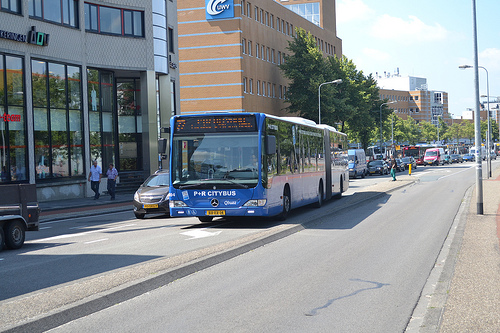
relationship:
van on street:
[423, 145, 446, 168] [340, 134, 473, 278]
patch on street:
[297, 241, 389, 324] [169, 226, 273, 302]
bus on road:
[167, 109, 352, 222] [0, 156, 498, 332]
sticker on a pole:
[472, 145, 484, 177] [466, 83, 493, 222]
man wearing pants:
[390, 155, 400, 182] [388, 168, 398, 182]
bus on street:
[164, 109, 354, 225] [1, 166, 483, 331]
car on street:
[132, 168, 176, 218] [1, 166, 483, 331]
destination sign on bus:
[173, 114, 256, 134] [164, 109, 354, 225]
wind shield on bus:
[173, 137, 262, 185] [164, 109, 354, 225]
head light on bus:
[237, 195, 269, 210] [164, 109, 354, 225]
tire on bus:
[279, 184, 292, 222] [164, 109, 354, 225]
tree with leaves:
[279, 25, 349, 134] [305, 65, 324, 82]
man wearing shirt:
[84, 157, 110, 203] [86, 163, 102, 183]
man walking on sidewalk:
[100, 158, 124, 201] [42, 193, 142, 230]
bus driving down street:
[164, 109, 354, 225] [1, 166, 483, 331]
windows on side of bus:
[269, 124, 329, 176] [164, 109, 354, 225]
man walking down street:
[86, 157, 102, 200] [1, 166, 483, 331]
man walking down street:
[100, 158, 124, 201] [1, 166, 483, 331]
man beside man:
[86, 157, 102, 200] [100, 158, 124, 201]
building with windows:
[1, 0, 179, 220] [6, 48, 150, 201]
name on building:
[0, 19, 56, 51] [1, 0, 179, 220]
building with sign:
[179, 2, 348, 165] [197, 0, 240, 23]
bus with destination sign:
[164, 109, 354, 225] [172, 115, 262, 136]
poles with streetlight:
[452, 4, 483, 217] [455, 63, 474, 74]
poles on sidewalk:
[452, 4, 483, 217] [401, 182, 481, 331]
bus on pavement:
[167, 109, 352, 222] [42, 222, 180, 254]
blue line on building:
[176, 93, 246, 103] [177, 0, 343, 117]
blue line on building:
[180, 80, 242, 90] [177, 0, 343, 117]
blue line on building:
[178, 55, 245, 65] [177, 0, 343, 117]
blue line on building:
[180, 41, 240, 52] [177, 0, 343, 117]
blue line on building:
[179, 27, 239, 39] [177, 0, 343, 117]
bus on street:
[164, 109, 354, 225] [0, 220, 267, 298]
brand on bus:
[208, 197, 219, 208] [167, 110, 350, 217]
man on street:
[390, 155, 400, 182] [349, 172, 461, 198]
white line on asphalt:
[79, 236, 110, 245] [42, 221, 141, 274]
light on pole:
[457, 63, 474, 73] [471, 60, 485, 182]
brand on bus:
[208, 197, 221, 208] [164, 109, 354, 225]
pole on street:
[405, 158, 410, 168] [1, 166, 483, 331]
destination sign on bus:
[172, 115, 262, 136] [163, 93, 358, 220]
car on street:
[124, 155, 173, 223] [47, 216, 170, 288]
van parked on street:
[342, 146, 367, 181] [346, 169, 442, 229]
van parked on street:
[423, 145, 446, 168] [405, 174, 444, 235]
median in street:
[6, 260, 146, 312] [295, 222, 397, 324]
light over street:
[457, 63, 473, 71] [417, 167, 460, 225]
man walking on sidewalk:
[86, 157, 102, 200] [73, 190, 123, 210]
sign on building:
[203, 0, 236, 22] [174, 2, 344, 112]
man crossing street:
[385, 155, 401, 187] [354, 180, 411, 246]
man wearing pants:
[385, 155, 401, 187] [389, 170, 399, 180]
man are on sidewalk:
[86, 157, 102, 200] [57, 192, 110, 212]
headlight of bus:
[246, 196, 266, 205] [164, 109, 354, 225]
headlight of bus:
[166, 198, 187, 208] [167, 109, 352, 222]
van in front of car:
[423, 145, 441, 165] [442, 152, 452, 164]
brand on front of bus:
[208, 197, 221, 208] [164, 109, 354, 225]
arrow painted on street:
[179, 222, 220, 238] [26, 224, 236, 289]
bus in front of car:
[164, 109, 354, 225] [132, 164, 167, 215]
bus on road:
[167, 109, 352, 222] [12, 212, 279, 308]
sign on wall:
[203, 0, 236, 22] [177, 2, 246, 112]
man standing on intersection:
[390, 155, 400, 182] [364, 157, 449, 185]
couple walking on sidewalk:
[85, 157, 123, 202] [7, 183, 137, 224]